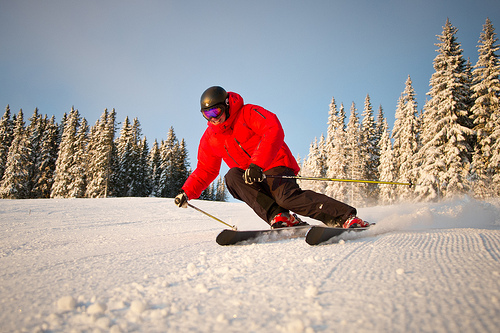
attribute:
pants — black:
[229, 163, 355, 223]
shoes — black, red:
[255, 206, 367, 228]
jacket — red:
[181, 91, 301, 198]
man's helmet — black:
[187, 81, 232, 119]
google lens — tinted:
[197, 106, 233, 119]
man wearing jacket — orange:
[158, 85, 380, 266]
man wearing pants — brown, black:
[167, 83, 378, 251]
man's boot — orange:
[262, 205, 308, 234]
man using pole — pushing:
[166, 78, 371, 263]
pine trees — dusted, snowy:
[3, 101, 188, 199]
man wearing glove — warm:
[154, 82, 372, 250]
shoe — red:
[259, 205, 302, 230]